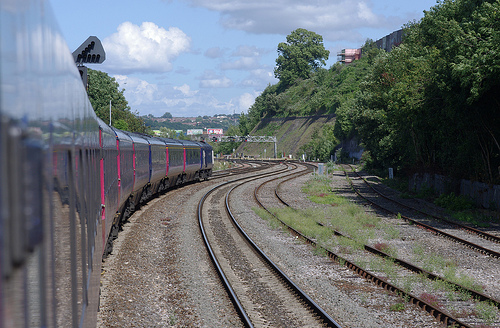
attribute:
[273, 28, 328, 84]
tree — green, big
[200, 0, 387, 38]
cloud — fluffy, grey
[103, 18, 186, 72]
cloud — white, fluffy